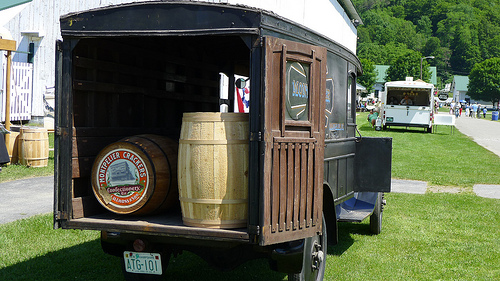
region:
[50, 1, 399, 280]
vintag paddy wagon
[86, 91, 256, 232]
two wooden barrels in back of vintage paddy wagon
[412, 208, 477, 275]
patch of green grass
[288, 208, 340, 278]
black wheel of paddy wagon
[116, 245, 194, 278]
green and white licence plate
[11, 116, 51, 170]
upright tan wood barrel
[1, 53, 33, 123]
white lattice fence on side of white building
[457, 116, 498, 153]
paved grey sidewalk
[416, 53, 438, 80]
metal tall street lamp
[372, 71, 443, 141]
back of white trunk parked in grass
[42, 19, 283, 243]
open door on truck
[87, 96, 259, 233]
two barrels in truck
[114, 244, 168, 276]
license plate on truck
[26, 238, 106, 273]
shadow of truck on grass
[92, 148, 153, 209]
label on bottom of barrel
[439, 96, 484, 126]
people walking in distance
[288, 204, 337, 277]
back tire of truck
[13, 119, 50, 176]
wood barrel on grass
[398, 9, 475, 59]
green leaves of trees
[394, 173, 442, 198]
flat stone in grass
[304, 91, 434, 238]
the grass is green and visible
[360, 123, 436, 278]
the grass is green and visible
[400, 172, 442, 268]
the grass is green and visible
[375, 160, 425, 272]
the grass is green and visible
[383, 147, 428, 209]
the grass is green and visible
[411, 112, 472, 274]
the grass is green and visible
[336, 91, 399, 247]
the grass is green and visible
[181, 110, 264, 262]
barrel inside of car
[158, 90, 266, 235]
barrel is brown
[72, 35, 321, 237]
car's back doors are open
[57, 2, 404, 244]
the car is black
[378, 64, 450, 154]
white vehicle in front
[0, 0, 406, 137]
the barn is white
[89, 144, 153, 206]
white lettering on barrel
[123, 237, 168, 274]
license plate is white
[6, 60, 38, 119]
white fence next to barn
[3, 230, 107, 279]
shadow of truck on ground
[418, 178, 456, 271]
the grass is green and visible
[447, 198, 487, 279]
the grass is green and visible